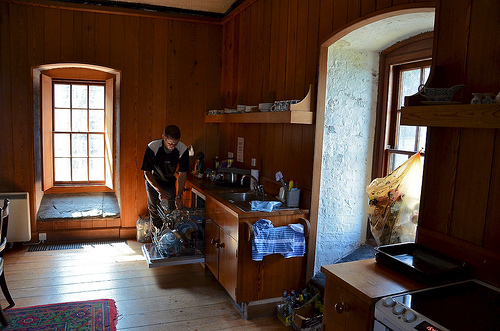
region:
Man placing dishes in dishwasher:
[137, 91, 207, 269]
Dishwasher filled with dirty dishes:
[141, 191, 206, 270]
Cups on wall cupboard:
[202, 83, 314, 126]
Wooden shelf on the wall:
[202, 84, 316, 129]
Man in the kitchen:
[127, 3, 499, 329]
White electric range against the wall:
[373, 278, 498, 328]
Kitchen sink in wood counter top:
[197, 168, 309, 315]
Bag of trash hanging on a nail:
[362, 138, 427, 252]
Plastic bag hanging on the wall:
[364, 146, 425, 251]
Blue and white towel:
[247, 214, 312, 261]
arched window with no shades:
[17, 55, 149, 286]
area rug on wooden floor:
[1, 285, 132, 326]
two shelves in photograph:
[172, 80, 486, 148]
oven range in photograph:
[274, 218, 495, 328]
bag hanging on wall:
[351, 137, 456, 288]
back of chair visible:
[2, 178, 56, 329]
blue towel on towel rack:
[228, 205, 325, 270]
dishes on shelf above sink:
[205, 80, 325, 152]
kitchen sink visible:
[211, 158, 325, 280]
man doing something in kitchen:
[94, 108, 228, 289]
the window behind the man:
[36, 55, 133, 212]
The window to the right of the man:
[317, 36, 434, 263]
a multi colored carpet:
[21, 290, 126, 330]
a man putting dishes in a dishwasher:
[144, 125, 188, 230]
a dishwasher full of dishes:
[153, 208, 210, 263]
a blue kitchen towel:
[247, 218, 324, 263]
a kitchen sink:
[221, 167, 285, 215]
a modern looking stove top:
[381, 277, 491, 329]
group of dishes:
[208, 99, 308, 131]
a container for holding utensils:
[271, 166, 306, 213]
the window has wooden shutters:
[36, 55, 123, 237]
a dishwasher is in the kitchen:
[139, 190, 208, 277]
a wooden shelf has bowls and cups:
[201, 87, 311, 134]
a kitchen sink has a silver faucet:
[206, 172, 303, 212]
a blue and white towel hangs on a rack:
[243, 217, 309, 291]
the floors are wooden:
[2, 242, 289, 329]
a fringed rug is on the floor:
[9, 278, 136, 329]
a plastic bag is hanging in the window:
[357, 143, 424, 259]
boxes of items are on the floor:
[274, 277, 324, 326]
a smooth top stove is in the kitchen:
[381, 277, 496, 327]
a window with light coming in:
[43, 71, 107, 185]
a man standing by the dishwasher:
[137, 125, 188, 223]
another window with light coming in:
[381, 66, 424, 201]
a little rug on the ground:
[16, 302, 113, 329]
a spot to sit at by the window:
[46, 190, 120, 217]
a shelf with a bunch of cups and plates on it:
[201, 100, 304, 135]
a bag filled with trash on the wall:
[369, 156, 414, 247]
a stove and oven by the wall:
[373, 270, 498, 330]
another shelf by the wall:
[393, 95, 497, 135]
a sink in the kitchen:
[225, 173, 285, 223]